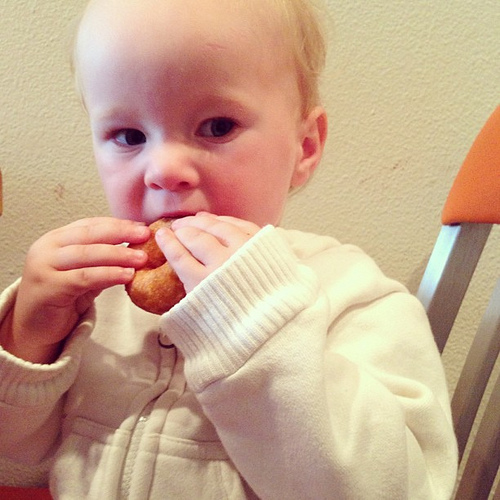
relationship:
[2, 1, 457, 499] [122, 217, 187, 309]
baby eating a donut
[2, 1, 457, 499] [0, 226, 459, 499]
baby wears a sweater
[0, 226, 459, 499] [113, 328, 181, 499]
sweater has zipper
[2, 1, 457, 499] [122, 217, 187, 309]
baby eating donut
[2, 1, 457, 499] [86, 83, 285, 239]
baby has face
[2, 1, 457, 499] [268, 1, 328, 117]
baby has hair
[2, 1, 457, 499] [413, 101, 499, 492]
baby sitting in chair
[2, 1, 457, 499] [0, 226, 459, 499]
baby wearing a sweater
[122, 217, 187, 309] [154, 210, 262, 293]
donut in hand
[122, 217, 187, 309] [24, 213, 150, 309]
donut in hand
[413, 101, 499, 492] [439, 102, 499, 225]
chair has stuff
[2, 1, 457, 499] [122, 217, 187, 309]
baby enjoying donut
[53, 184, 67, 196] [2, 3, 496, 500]
food on wall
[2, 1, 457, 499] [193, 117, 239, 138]
baby has eye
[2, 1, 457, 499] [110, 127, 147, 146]
baby has eye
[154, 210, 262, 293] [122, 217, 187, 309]
hand holding donut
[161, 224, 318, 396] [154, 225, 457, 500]
cuff on edge of sleeve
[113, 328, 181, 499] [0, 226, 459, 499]
zipper in front of sweater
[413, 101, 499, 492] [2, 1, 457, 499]
chair on side of baby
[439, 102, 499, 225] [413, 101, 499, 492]
stuff on top of chair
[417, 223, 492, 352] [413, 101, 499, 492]
bar on back of chair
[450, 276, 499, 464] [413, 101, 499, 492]
bar on back of chair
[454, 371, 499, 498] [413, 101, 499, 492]
bar on back of chair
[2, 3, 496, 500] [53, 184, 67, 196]
wall has food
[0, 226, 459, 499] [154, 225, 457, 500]
sweater has sleeve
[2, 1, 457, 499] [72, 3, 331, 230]
baby has head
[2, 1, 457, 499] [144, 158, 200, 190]
baby has nose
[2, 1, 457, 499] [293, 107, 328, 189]
baby has ear